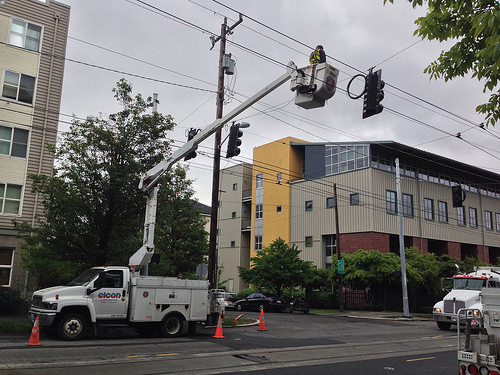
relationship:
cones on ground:
[211, 313, 227, 338] [183, 335, 325, 355]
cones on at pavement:
[211, 313, 227, 340] [0, 311, 465, 374]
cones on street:
[24, 304, 273, 342] [4, 294, 342, 363]